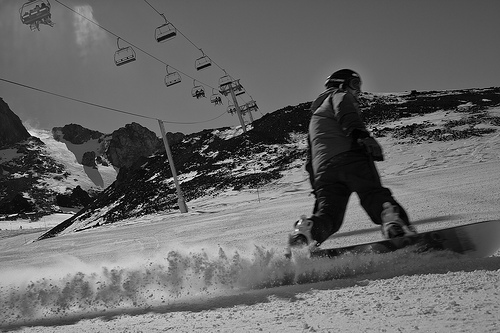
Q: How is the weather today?
A: It is clear.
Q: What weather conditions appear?
A: It is clear.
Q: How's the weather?
A: It is clear.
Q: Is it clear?
A: Yes, it is clear.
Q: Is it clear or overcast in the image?
A: It is clear.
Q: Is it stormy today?
A: No, it is clear.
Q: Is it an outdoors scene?
A: Yes, it is outdoors.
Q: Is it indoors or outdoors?
A: It is outdoors.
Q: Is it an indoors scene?
A: No, it is outdoors.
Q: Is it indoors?
A: No, it is outdoors.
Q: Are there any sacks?
A: No, there are no sacks.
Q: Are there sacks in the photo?
A: No, there are no sacks.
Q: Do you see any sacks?
A: No, there are no sacks.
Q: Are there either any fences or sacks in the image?
A: No, there are no sacks or fences.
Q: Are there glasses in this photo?
A: No, there are no glasses.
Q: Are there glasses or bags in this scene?
A: No, there are no glasses or bags.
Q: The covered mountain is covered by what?
A: The mountain is covered by the snow.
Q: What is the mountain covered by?
A: The mountain is covered by the snow.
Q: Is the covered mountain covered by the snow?
A: Yes, the mountain is covered by the snow.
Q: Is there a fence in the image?
A: No, there are no fences.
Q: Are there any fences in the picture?
A: No, there are no fences.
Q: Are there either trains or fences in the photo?
A: No, there are no fences or trains.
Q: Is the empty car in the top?
A: Yes, the car is in the top of the image.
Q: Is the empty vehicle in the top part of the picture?
A: Yes, the car is in the top of the image.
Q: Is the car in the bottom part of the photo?
A: No, the car is in the top of the image.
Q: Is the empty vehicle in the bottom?
A: No, the car is in the top of the image.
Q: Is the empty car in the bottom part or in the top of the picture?
A: The car is in the top of the image.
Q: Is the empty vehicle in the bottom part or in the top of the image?
A: The car is in the top of the image.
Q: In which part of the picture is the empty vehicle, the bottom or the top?
A: The car is in the top of the image.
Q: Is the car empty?
A: Yes, the car is empty.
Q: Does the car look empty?
A: Yes, the car is empty.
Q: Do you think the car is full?
A: No, the car is empty.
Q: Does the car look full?
A: No, the car is empty.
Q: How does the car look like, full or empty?
A: The car is empty.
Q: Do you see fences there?
A: No, there are no fences.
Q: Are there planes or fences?
A: No, there are no fences or planes.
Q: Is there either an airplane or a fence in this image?
A: No, there are no fences or airplanes.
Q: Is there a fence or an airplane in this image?
A: No, there are no fences or airplanes.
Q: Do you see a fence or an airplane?
A: No, there are no fences or airplanes.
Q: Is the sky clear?
A: Yes, the sky is clear.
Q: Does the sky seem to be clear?
A: Yes, the sky is clear.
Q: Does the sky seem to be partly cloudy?
A: No, the sky is clear.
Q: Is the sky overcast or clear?
A: The sky is clear.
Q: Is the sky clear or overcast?
A: The sky is clear.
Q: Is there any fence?
A: No, there are no fences.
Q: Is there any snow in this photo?
A: Yes, there is snow.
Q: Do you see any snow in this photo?
A: Yes, there is snow.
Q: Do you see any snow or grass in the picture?
A: Yes, there is snow.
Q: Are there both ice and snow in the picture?
A: No, there is snow but no ice.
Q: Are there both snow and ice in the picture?
A: No, there is snow but no ice.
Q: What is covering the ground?
A: The snow is covering the ground.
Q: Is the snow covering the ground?
A: Yes, the snow is covering the ground.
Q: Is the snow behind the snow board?
A: Yes, the snow is behind the snow board.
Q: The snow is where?
A: The snow is on the mountain.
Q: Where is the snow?
A: The snow is on the mountain.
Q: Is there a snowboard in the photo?
A: Yes, there is a snowboard.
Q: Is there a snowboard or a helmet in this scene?
A: Yes, there is a snowboard.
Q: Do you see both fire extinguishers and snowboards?
A: No, there is a snowboard but no fire extinguishers.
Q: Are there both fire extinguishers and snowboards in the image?
A: No, there is a snowboard but no fire extinguishers.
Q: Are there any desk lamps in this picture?
A: No, there are no desk lamps.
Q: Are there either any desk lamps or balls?
A: No, there are no desk lamps or balls.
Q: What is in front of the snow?
A: The snowboard is in front of the snow.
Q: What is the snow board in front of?
A: The snow board is in front of the snow.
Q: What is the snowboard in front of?
A: The snow board is in front of the snow.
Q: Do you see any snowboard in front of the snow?
A: Yes, there is a snowboard in front of the snow.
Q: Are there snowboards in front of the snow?
A: Yes, there is a snowboard in front of the snow.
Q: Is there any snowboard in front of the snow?
A: Yes, there is a snowboard in front of the snow.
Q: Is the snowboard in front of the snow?
A: Yes, the snowboard is in front of the snow.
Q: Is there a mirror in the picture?
A: No, there are no mirrors.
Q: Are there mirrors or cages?
A: No, there are no mirrors or cages.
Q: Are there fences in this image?
A: No, there are no fences.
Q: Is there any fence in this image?
A: No, there are no fences.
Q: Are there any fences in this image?
A: No, there are no fences.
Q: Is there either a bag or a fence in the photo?
A: No, there are no fences or bags.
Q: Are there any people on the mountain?
A: Yes, there is a person on the mountain.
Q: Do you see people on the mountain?
A: Yes, there is a person on the mountain.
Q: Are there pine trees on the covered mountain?
A: No, there is a person on the mountain.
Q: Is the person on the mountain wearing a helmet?
A: Yes, the person is wearing a helmet.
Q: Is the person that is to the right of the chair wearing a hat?
A: No, the person is wearing a helmet.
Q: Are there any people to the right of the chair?
A: Yes, there is a person to the right of the chair.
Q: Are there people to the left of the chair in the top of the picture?
A: No, the person is to the right of the chair.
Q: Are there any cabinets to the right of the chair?
A: No, there is a person to the right of the chair.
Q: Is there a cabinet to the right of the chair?
A: No, there is a person to the right of the chair.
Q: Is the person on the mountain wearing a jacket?
A: Yes, the person is wearing a jacket.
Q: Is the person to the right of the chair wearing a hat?
A: No, the person is wearing a jacket.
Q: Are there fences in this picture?
A: No, there are no fences.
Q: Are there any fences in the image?
A: No, there are no fences.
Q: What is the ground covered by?
A: The ground is covered by the snow.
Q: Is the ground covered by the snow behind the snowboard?
A: Yes, the ground is covered by the snow.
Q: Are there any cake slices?
A: No, there are no cake slices.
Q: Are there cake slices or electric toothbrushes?
A: No, there are no cake slices or electric toothbrushes.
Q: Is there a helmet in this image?
A: Yes, there is a helmet.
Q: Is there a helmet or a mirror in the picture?
A: Yes, there is a helmet.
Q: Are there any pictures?
A: No, there are no pictures.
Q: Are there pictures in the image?
A: No, there are no pictures.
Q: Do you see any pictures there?
A: No, there are no pictures.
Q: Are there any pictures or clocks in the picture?
A: No, there are no pictures or clocks.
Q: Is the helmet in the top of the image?
A: Yes, the helmet is in the top of the image.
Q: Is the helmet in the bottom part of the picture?
A: No, the helmet is in the top of the image.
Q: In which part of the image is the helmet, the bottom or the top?
A: The helmet is in the top of the image.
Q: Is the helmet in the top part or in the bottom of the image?
A: The helmet is in the top of the image.